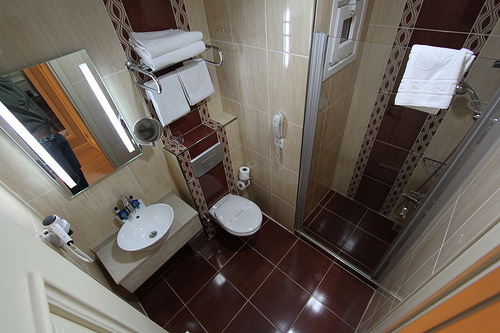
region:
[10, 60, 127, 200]
This is a mirror.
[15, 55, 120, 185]
The mirror is made of glass.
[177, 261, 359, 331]
The ground here is tile.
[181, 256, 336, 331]
This tile is brown.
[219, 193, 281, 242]
This is a toilet.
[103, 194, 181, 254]
This is a sink.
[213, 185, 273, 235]
The toilet is white.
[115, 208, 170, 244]
The sink here is white.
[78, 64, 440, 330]
This is in a bathroom.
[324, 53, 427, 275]
This is the shower.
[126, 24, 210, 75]
TWO FOLDED WHITE TOWELS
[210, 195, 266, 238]
A WHITE TOILET SEAT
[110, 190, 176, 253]
A WHITE BATHROOM SINK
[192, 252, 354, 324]
BROWN FLOOR TILES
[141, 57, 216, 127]
TWO WHITE HAND TOWELS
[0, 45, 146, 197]
A BATHROOM MIRROR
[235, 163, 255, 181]
A ROLL OF TOILET PAPER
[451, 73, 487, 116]
A METAL SHOWER HEAD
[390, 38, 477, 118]
A TOWEL ON THE SHOWER DOOR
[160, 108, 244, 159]
A GLASS SHELF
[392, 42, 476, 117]
Bath towel hung over glass shower partition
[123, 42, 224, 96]
Metal towel rack mounted to the wall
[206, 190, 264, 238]
White toilet with the lid down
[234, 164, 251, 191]
A couple of rolls of toilet tissue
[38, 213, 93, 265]
A hair blow dryer attached to the wall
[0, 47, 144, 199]
A rectangular bathroom mirror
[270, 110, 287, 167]
A white wall mounted telephone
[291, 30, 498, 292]
A shower with glass door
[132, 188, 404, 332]
Shiny brown bathroom tile on the floor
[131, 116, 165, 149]
A round swivel mirror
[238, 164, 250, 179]
the toilet roll on the toilet roll dispenser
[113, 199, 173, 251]
the white bathroom sink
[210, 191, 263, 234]
the white toilet bowl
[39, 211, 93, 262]
the hairdryer hanging on the wall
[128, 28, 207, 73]
the towels folded on the shelf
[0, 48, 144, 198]
the bathroom mirror above the sink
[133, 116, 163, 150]
the round mirror near the sink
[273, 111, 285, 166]
the telephone next to the toilet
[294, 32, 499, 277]
the glass shower door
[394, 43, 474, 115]
the towel hanging over the glass shower door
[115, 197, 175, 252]
a white porcelain bathroom sink basin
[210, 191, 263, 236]
a white porcelain toilet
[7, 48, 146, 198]
a wall mounted mirror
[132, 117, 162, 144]
a small round vanity mirror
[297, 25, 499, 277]
a glass shower door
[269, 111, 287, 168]
a telephone handset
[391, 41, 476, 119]
a hanging white towel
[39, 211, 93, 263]
a white hair dryer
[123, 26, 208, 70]
a stack of folded white towels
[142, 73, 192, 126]
a hanging white towel